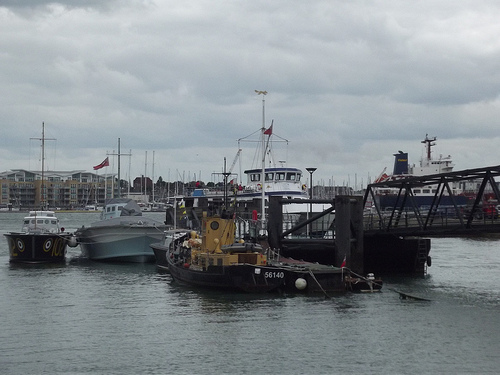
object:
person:
[238, 185, 242, 192]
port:
[0, 82, 500, 373]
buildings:
[65, 171, 107, 209]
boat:
[3, 209, 73, 265]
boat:
[163, 186, 348, 293]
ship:
[182, 90, 336, 236]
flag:
[92, 157, 110, 170]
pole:
[117, 136, 122, 202]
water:
[213, 300, 358, 368]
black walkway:
[362, 163, 499, 237]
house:
[132, 177, 155, 193]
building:
[0, 168, 37, 207]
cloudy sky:
[1, 0, 500, 188]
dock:
[154, 193, 431, 278]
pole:
[260, 97, 266, 236]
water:
[0, 266, 155, 373]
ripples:
[62, 279, 187, 359]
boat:
[366, 132, 499, 214]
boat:
[74, 199, 170, 263]